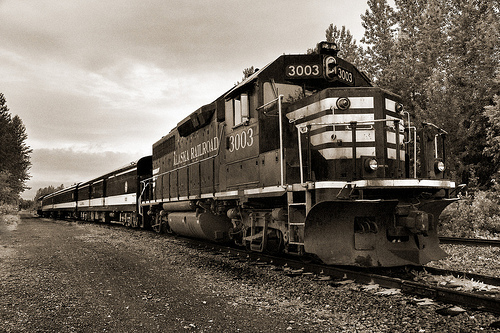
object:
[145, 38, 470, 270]
engine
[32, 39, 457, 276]
train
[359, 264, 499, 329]
tracks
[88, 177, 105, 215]
car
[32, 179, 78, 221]
car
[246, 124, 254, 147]
number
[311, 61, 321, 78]
number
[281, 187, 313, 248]
ladder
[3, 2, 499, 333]
photograph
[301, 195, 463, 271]
plow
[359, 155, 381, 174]
light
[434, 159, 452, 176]
light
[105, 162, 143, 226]
cabins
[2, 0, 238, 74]
sky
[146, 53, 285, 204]
side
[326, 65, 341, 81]
headlight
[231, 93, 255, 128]
window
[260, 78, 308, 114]
window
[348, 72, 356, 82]
number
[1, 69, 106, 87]
clouds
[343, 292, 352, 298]
gravel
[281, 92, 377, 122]
strips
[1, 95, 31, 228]
tree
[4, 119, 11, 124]
leaves